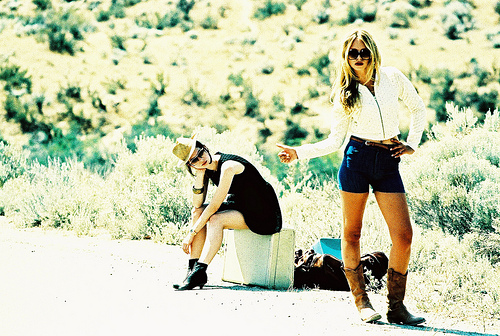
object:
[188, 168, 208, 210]
right hand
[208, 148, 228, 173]
neck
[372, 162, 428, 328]
legs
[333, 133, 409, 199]
shorts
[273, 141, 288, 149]
her thumb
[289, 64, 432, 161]
shirt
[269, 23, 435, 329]
lady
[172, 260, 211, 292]
boot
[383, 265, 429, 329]
boot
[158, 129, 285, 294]
girl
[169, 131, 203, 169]
dress hat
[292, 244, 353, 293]
bag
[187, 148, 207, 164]
sunglasses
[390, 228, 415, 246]
knee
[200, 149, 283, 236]
black dress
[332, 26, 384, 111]
hair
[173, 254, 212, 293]
booties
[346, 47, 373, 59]
sunglasses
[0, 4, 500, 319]
ground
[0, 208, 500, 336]
road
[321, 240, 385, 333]
foot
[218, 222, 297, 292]
bag